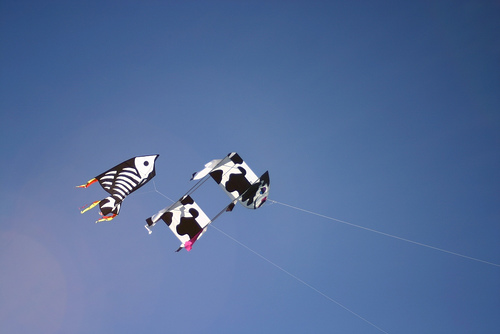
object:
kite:
[144, 152, 271, 253]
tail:
[144, 195, 212, 253]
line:
[268, 199, 500, 266]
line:
[155, 190, 332, 300]